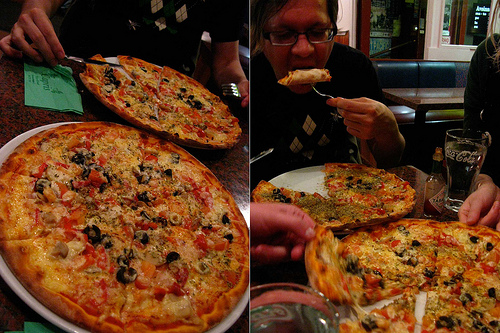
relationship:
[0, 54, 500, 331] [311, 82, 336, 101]
pizza on fork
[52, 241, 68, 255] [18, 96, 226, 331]
sausage on pizza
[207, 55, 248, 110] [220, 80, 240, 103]
hand holding phone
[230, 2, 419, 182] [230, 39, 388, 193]
person wearing shirt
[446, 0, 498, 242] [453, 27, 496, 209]
person wearing shirt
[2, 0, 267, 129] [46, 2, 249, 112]
person wearing shirt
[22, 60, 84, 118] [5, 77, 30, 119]
napkin on table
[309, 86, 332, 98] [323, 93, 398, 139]
fork in hand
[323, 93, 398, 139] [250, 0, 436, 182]
hand of person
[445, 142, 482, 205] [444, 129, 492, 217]
dark liquid in cup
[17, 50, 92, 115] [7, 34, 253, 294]
envelope on surface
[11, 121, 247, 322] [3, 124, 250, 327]
pizza on white plate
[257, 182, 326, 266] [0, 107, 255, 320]
fingers on pizza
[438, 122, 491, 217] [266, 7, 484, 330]
glass in photo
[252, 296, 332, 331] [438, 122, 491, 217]
water in glass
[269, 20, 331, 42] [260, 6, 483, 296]
eyeglasses in photo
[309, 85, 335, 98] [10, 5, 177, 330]
fork in photo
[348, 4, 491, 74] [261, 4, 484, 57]
window in background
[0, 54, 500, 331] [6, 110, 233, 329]
pizza in slices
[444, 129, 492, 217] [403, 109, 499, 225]
cup in cup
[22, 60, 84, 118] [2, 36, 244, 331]
napkin on table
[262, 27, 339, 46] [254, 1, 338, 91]
eyeglasses on face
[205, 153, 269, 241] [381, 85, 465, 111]
reflection on table